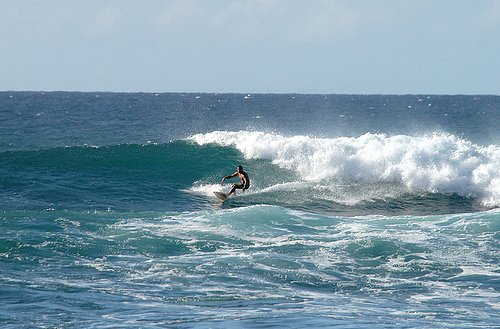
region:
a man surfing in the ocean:
[209, 155, 257, 208]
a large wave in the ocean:
[270, 115, 482, 186]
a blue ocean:
[127, 240, 292, 300]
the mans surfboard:
[210, 189, 230, 211]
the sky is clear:
[228, 13, 345, 73]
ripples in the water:
[153, 229, 326, 308]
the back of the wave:
[60, 132, 170, 173]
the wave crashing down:
[266, 127, 472, 209]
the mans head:
[235, 160, 247, 176]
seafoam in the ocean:
[313, 138, 451, 299]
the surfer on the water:
[205, 159, 257, 201]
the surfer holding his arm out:
[216, 162, 251, 197]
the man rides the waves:
[205, 160, 257, 207]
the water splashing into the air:
[248, 175, 310, 205]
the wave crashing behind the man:
[286, 135, 498, 207]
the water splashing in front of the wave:
[325, 176, 394, 207]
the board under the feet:
[213, 189, 233, 200]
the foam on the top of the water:
[179, 223, 496, 310]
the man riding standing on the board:
[205, 156, 262, 208]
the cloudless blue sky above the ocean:
[2, 10, 454, 76]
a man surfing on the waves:
[28, 86, 459, 292]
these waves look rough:
[193, 126, 499, 228]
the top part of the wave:
[22, 123, 215, 156]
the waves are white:
[257, 116, 484, 202]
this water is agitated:
[143, 206, 480, 317]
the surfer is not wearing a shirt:
[212, 157, 260, 206]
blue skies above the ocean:
[20, 13, 466, 68]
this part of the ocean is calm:
[11, 83, 471, 124]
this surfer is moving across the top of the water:
[43, 140, 278, 215]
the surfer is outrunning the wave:
[168, 121, 469, 231]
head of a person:
[233, 162, 247, 172]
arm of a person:
[222, 173, 240, 183]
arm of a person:
[239, 178, 257, 189]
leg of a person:
[225, 179, 242, 197]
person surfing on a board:
[165, 152, 260, 254]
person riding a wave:
[202, 132, 272, 204]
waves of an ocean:
[260, 122, 494, 200]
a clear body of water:
[237, 232, 479, 297]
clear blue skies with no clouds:
[139, 28, 323, 79]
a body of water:
[40, 105, 205, 130]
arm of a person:
[220, 170, 233, 182]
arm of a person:
[243, 175, 248, 190]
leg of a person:
[228, 177, 247, 194]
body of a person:
[237, 171, 252, 181]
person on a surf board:
[198, 142, 265, 224]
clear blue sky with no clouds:
[223, 37, 375, 77]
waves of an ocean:
[286, 117, 498, 207]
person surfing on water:
[185, 145, 277, 216]